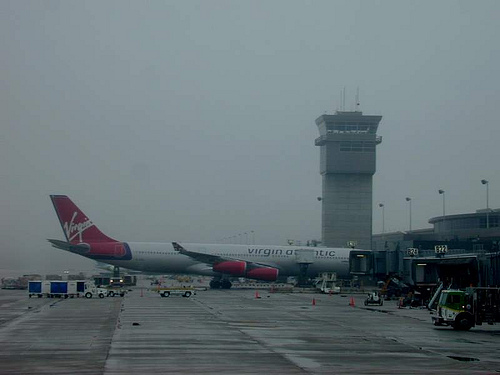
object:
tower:
[315, 83, 385, 248]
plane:
[39, 190, 372, 289]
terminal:
[350, 241, 500, 285]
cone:
[348, 294, 358, 308]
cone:
[309, 297, 314, 306]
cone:
[251, 290, 261, 299]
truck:
[25, 277, 49, 299]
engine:
[214, 259, 279, 281]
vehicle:
[155, 283, 198, 300]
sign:
[243, 246, 337, 259]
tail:
[44, 191, 127, 264]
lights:
[477, 177, 490, 210]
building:
[313, 211, 500, 286]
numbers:
[433, 245, 450, 254]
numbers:
[405, 247, 420, 257]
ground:
[1, 277, 499, 375]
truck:
[426, 286, 499, 333]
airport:
[297, 211, 499, 314]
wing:
[169, 239, 285, 280]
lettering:
[62, 211, 76, 243]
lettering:
[326, 246, 337, 259]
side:
[74, 241, 366, 292]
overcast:
[1, 0, 499, 277]